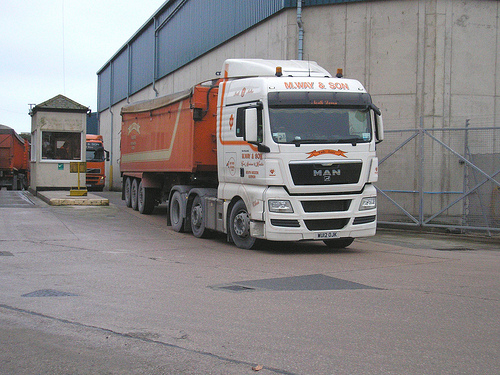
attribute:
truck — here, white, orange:
[118, 56, 380, 255]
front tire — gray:
[225, 198, 255, 250]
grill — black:
[254, 187, 382, 247]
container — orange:
[110, 78, 222, 183]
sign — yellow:
[71, 162, 92, 175]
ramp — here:
[0, 185, 33, 207]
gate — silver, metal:
[382, 128, 497, 236]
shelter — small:
[27, 93, 93, 191]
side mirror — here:
[234, 105, 269, 150]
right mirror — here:
[365, 103, 391, 150]